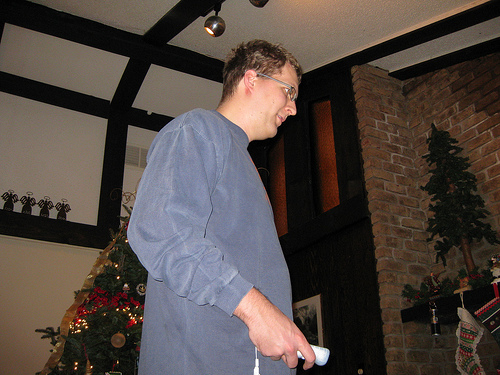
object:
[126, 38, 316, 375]
person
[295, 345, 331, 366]
remote control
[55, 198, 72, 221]
decoration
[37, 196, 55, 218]
decoration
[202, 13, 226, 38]
light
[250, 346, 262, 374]
tassel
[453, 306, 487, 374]
stocking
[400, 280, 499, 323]
mantel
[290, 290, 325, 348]
picture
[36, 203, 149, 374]
tree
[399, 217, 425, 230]
brick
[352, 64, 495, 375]
wall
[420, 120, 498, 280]
tree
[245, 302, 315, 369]
hand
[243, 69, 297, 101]
glasses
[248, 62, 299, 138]
face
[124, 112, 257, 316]
sleeve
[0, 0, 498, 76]
ceiling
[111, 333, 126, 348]
ornament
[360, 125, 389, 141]
brick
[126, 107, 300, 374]
shirt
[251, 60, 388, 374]
wall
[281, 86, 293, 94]
eye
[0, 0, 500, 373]
background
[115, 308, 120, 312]
christmas light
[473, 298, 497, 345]
stocking